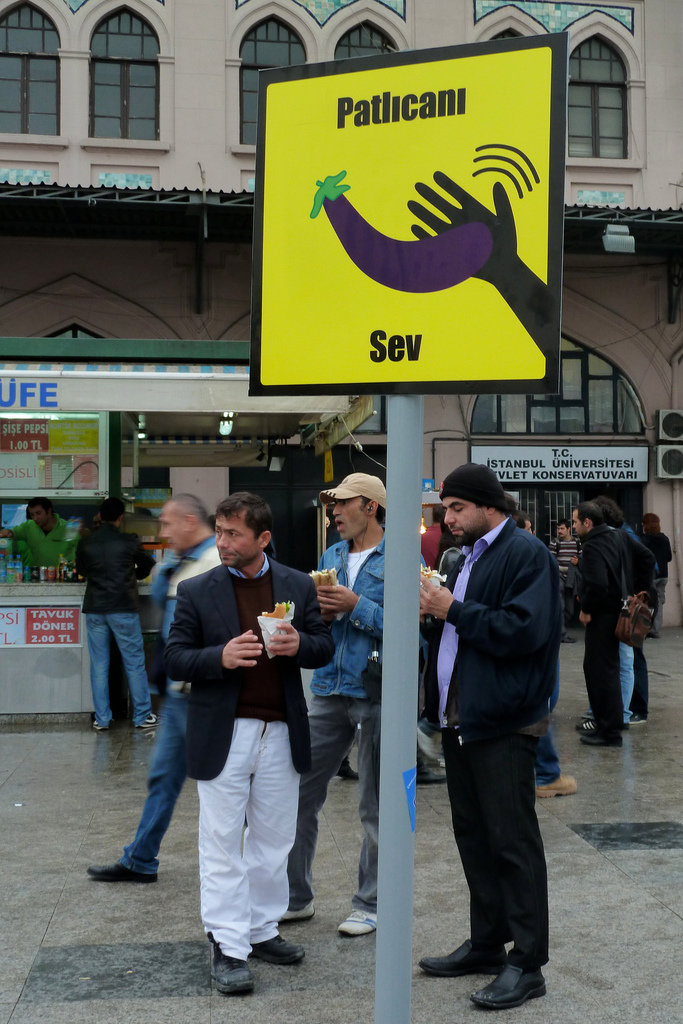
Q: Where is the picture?
A: Outside of the Patlicani Sev sign.